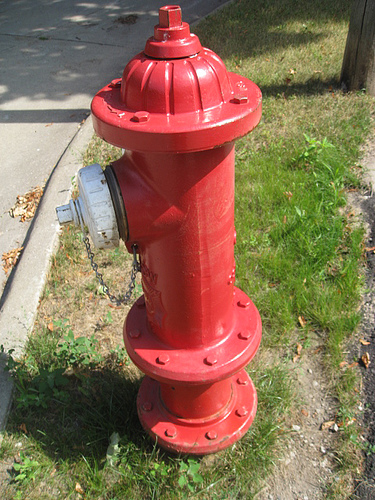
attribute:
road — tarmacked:
[2, 3, 84, 123]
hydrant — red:
[83, 3, 262, 488]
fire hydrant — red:
[89, 2, 264, 458]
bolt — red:
[159, 4, 182, 24]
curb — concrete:
[2, 166, 79, 416]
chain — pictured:
[82, 237, 139, 306]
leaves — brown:
[34, 176, 67, 234]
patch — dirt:
[260, 332, 344, 498]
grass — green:
[242, 160, 340, 287]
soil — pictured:
[259, 317, 332, 499]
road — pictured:
[23, 22, 121, 134]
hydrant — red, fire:
[113, 17, 280, 360]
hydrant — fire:
[33, 29, 326, 472]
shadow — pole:
[0, 98, 98, 140]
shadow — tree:
[2, 1, 367, 91]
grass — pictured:
[238, 155, 371, 294]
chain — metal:
[78, 228, 140, 306]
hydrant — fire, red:
[49, 4, 274, 458]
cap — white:
[69, 11, 295, 147]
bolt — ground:
[163, 424, 173, 441]